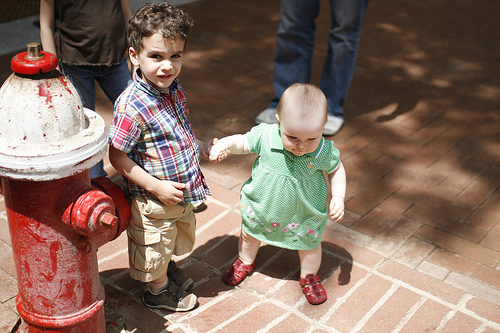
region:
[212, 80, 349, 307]
baby in green dress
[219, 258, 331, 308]
sandals on baby's feet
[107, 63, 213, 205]
plaid shirt on boy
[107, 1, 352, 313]
two small children holding hands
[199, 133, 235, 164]
boy and girl hands clasped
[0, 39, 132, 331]
fire hydrant beside children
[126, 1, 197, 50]
boy's hair is curly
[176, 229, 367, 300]
shadows of children on ground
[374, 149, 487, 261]
brick inlay on ground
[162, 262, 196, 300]
velcro straps on shoes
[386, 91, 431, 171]
part of a shade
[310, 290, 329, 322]
par tof a shoe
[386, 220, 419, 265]
part of a floor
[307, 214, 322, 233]
part of a cloth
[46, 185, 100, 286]
part of a tankl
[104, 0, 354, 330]
two children are sanding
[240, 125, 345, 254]
the dress is green in colour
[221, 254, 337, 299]
the shoes are red in colour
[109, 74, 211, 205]
the shirt ismulticoloured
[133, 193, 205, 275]
the pants are brown in colour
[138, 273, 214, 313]
the shoes are black in colour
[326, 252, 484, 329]
the floor is brown in colour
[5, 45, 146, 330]
the water pump is old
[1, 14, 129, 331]
it is red in colour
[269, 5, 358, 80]
the pants areblue in colour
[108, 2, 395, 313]
Toddler boy holding a baby girl's hand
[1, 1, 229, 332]
Little boy standing next to a fire hydrant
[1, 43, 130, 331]
Fire hydrant with red base and white top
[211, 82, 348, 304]
Baby in a green dress with flowers on the bottom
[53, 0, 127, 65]
Belly of a pregnant woman in a brown shirt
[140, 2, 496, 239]
Shadow of a tree on the sidewalk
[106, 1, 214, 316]
Little boy in a colorful shirt and khaki cargo shorts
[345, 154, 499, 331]
Section of a brick sidewalk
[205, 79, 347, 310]
Baby girl wearing red sandals and white tights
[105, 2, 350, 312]
Brother and baby sister hold hands in the sunlight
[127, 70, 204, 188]
a striped coloured shirt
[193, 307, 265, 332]
the floor has square slabs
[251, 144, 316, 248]
the dress is green in colour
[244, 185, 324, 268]
the dress has flowers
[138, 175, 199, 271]
he short is brown in colour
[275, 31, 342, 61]
the pants are blue in colour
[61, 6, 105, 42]
the shirt is brown in colour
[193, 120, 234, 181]
the children are holding hands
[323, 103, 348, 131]
the shoes are white in colour